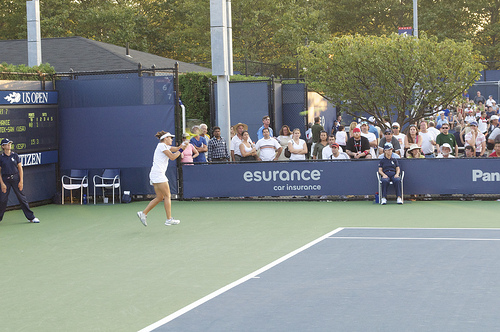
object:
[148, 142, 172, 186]
uniform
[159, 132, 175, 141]
visor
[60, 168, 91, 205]
chair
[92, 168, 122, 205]
chair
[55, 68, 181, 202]
wall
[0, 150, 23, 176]
shirt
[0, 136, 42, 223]
man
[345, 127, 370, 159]
man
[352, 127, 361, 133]
red hat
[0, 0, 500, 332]
outside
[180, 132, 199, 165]
woman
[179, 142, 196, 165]
pink shirt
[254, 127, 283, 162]
people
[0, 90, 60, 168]
scoreboard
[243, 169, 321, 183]
esurance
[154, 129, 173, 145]
player's head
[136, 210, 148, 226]
tennis shoes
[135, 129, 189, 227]
woman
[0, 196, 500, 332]
ground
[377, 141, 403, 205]
woman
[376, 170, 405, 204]
chair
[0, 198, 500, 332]
court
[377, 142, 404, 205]
attendant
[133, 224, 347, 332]
line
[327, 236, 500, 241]
line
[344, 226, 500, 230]
line